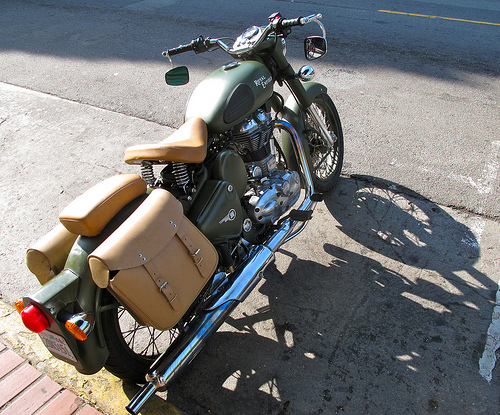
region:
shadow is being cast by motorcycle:
[155, 168, 497, 412]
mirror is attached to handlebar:
[160, 50, 194, 85]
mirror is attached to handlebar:
[298, 18, 330, 58]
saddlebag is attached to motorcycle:
[87, 184, 224, 335]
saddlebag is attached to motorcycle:
[24, 215, 76, 287]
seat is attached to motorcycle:
[122, 115, 210, 177]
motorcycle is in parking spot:
[18, 10, 355, 411]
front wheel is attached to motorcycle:
[282, 71, 346, 192]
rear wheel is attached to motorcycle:
[92, 213, 194, 395]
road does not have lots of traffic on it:
[0, 0, 497, 411]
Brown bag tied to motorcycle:
[87, 252, 227, 312]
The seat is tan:
[107, 126, 215, 174]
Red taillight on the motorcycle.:
[15, 299, 57, 340]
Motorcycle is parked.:
[83, 108, 380, 298]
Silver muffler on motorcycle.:
[158, 274, 232, 390]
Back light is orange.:
[62, 312, 88, 350]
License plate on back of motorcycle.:
[34, 329, 67, 359]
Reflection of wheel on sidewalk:
[334, 155, 473, 285]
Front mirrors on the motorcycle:
[306, 37, 336, 60]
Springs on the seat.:
[141, 161, 188, 189]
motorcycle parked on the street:
[34, 45, 406, 365]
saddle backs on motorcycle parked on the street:
[97, 208, 243, 328]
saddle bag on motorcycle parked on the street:
[186, 160, 248, 255]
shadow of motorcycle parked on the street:
[333, 148, 487, 414]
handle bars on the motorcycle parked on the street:
[122, 14, 358, 86]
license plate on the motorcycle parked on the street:
[33, 325, 80, 359]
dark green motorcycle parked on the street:
[7, 35, 411, 407]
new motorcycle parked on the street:
[21, 33, 438, 374]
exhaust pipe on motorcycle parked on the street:
[156, 276, 276, 398]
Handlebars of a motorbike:
[159, 12, 323, 66]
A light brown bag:
[85, 184, 222, 335]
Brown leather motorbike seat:
[119, 114, 213, 170]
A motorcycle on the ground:
[11, 9, 355, 413]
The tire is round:
[288, 84, 348, 197]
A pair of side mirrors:
[160, 31, 332, 91]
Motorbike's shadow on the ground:
[161, 168, 499, 413]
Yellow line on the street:
[376, 3, 498, 33]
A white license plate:
[32, 318, 79, 366]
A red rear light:
[16, 297, 54, 337]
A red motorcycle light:
[17, 295, 55, 332]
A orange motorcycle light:
[65, 311, 93, 341]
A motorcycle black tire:
[282, 82, 355, 194]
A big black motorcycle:
[22, 4, 348, 410]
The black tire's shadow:
[311, 170, 479, 280]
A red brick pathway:
[0, 341, 100, 413]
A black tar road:
[367, 102, 461, 162]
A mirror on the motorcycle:
[298, 34, 328, 59]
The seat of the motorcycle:
[120, 114, 217, 164]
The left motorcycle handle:
[158, 31, 225, 58]